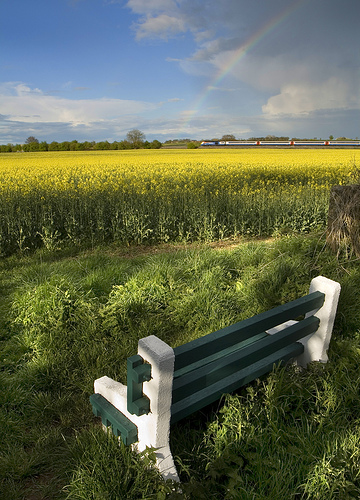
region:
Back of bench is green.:
[159, 345, 326, 371]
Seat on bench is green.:
[120, 369, 241, 412]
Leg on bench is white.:
[90, 362, 173, 485]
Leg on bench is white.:
[299, 273, 346, 364]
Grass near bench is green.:
[230, 436, 305, 474]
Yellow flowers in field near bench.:
[21, 162, 54, 217]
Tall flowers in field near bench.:
[85, 177, 196, 208]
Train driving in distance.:
[193, 132, 359, 163]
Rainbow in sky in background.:
[158, 27, 288, 111]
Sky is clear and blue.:
[30, 13, 108, 83]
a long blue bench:
[59, 269, 356, 438]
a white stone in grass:
[138, 322, 196, 493]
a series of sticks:
[186, 325, 283, 414]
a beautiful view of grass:
[25, 243, 355, 450]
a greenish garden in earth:
[0, 150, 353, 243]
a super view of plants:
[26, 131, 357, 227]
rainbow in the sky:
[184, 38, 276, 103]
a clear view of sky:
[19, 14, 351, 142]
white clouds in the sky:
[66, 7, 337, 112]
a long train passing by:
[200, 132, 358, 150]